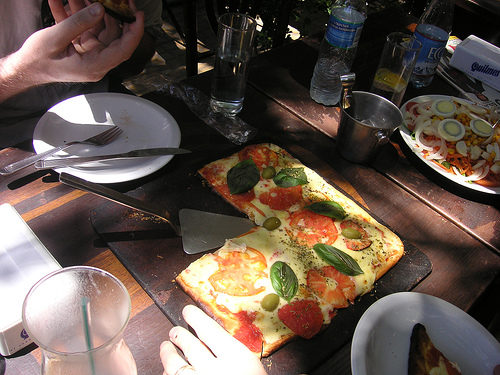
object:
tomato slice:
[278, 299, 323, 339]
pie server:
[59, 172, 257, 255]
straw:
[81, 296, 99, 374]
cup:
[22, 266, 132, 375]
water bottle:
[310, 0, 367, 106]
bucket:
[335, 91, 403, 163]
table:
[0, 0, 500, 375]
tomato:
[284, 210, 338, 248]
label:
[324, 13, 364, 49]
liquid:
[211, 48, 250, 103]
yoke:
[443, 121, 462, 136]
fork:
[0, 126, 123, 177]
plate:
[351, 291, 500, 375]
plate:
[398, 94, 500, 194]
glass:
[209, 12, 257, 118]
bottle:
[399, 9, 455, 88]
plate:
[33, 92, 183, 184]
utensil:
[0, 126, 192, 177]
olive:
[260, 293, 280, 312]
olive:
[262, 216, 281, 231]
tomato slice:
[208, 246, 268, 296]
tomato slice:
[306, 265, 355, 308]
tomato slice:
[238, 145, 279, 172]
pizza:
[175, 142, 405, 360]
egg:
[437, 118, 465, 141]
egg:
[431, 98, 457, 118]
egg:
[469, 117, 493, 137]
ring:
[171, 364, 191, 374]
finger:
[160, 340, 194, 375]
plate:
[89, 140, 432, 375]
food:
[401, 96, 499, 187]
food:
[101, 0, 137, 25]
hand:
[1, 0, 145, 102]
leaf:
[270, 261, 298, 306]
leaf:
[313, 243, 364, 276]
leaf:
[303, 200, 349, 220]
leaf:
[227, 156, 260, 195]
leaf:
[273, 167, 310, 188]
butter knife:
[34, 148, 192, 170]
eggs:
[431, 98, 494, 141]